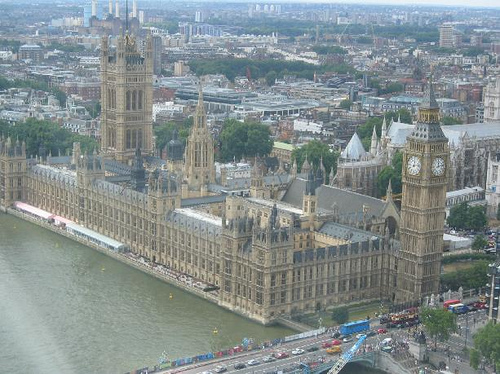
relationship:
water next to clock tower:
[0, 209, 305, 371] [399, 77, 451, 306]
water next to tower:
[0, 209, 305, 371] [100, 21, 152, 163]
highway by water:
[134, 288, 499, 372] [0, 209, 305, 371]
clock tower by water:
[399, 77, 451, 306] [0, 209, 305, 371]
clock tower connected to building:
[399, 77, 451, 306] [0, 30, 451, 322]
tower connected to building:
[98, 29, 157, 165] [0, 30, 451, 322]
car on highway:
[292, 348, 306, 355] [134, 288, 499, 372]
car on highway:
[325, 345, 341, 354] [134, 288, 499, 372]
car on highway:
[231, 361, 245, 369] [134, 288, 499, 372]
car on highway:
[262, 355, 274, 362] [134, 288, 499, 372]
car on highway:
[328, 337, 342, 345] [134, 288, 499, 372]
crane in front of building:
[318, 331, 369, 371] [0, 30, 451, 322]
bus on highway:
[446, 295, 461, 305] [141, 294, 498, 371]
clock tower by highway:
[399, 77, 444, 306] [134, 288, 499, 372]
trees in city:
[17, 112, 458, 162] [33, 18, 482, 358]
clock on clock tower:
[430, 157, 446, 178] [399, 77, 451, 306]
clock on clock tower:
[406, 157, 421, 174] [399, 77, 451, 306]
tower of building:
[80, 29, 205, 134] [47, 59, 445, 287]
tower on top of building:
[186, 80, 216, 185] [0, 30, 451, 322]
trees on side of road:
[417, 298, 499, 369] [366, 327, 401, 345]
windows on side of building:
[38, 175, 389, 293] [23, 134, 390, 297]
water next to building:
[0, 209, 305, 371] [3, 87, 459, 326]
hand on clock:
[436, 158, 439, 168] [423, 153, 465, 201]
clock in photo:
[406, 157, 421, 174] [0, 0, 499, 371]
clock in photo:
[430, 157, 446, 178] [0, 0, 499, 371]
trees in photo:
[220, 114, 282, 171] [0, 0, 499, 371]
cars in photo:
[236, 350, 329, 363] [0, 0, 499, 371]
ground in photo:
[384, 156, 414, 205] [0, 0, 499, 371]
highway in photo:
[134, 288, 499, 372] [0, 0, 499, 371]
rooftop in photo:
[47, 154, 350, 252] [0, 0, 499, 371]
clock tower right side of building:
[399, 77, 451, 306] [0, 30, 451, 322]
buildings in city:
[28, 5, 493, 273] [2, 1, 499, 371]